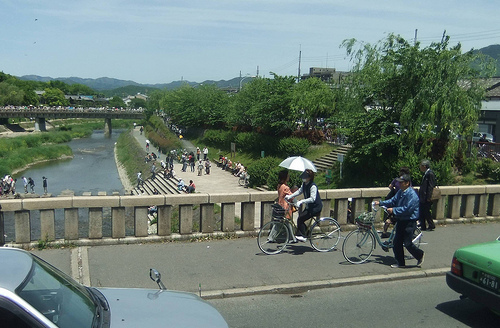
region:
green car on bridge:
[444, 235, 498, 312]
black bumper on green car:
[443, 269, 498, 305]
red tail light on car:
[448, 256, 462, 277]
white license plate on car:
[477, 272, 498, 287]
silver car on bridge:
[0, 245, 230, 326]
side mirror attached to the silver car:
[147, 267, 169, 292]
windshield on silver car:
[15, 253, 107, 325]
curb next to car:
[195, 263, 451, 300]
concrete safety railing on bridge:
[1, 193, 275, 247]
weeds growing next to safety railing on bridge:
[33, 237, 63, 253]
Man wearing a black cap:
[388, 171, 413, 188]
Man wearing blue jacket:
[373, 188, 440, 219]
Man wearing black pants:
[391, 215, 428, 278]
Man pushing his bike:
[337, 171, 437, 277]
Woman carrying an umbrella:
[270, 145, 322, 178]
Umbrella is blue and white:
[276, 149, 323, 180]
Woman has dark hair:
[271, 168, 298, 188]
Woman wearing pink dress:
[276, 185, 291, 222]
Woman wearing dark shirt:
[287, 168, 333, 203]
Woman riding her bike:
[261, 172, 341, 260]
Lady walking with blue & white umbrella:
[274, 156, 299, 192]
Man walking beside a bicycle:
[352, 176, 434, 271]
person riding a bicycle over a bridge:
[266, 169, 341, 234]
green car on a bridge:
[451, 234, 498, 296]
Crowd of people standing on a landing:
[161, 148, 255, 188]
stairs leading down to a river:
[318, 139, 343, 175]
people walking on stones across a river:
[0, 171, 55, 196]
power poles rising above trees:
[223, 61, 317, 81]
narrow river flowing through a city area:
[71, 125, 125, 196]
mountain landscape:
[20, 70, 182, 102]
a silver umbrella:
[274, 152, 320, 174]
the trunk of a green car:
[444, 225, 499, 298]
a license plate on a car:
[477, 268, 497, 288]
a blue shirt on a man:
[380, 185, 425, 220]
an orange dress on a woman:
[267, 180, 292, 221]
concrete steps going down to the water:
[125, 170, 197, 195]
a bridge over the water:
[5, 95, 165, 150]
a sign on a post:
[330, 150, 345, 177]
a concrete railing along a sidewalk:
[0, 180, 492, 240]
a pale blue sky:
[2, 4, 499, 84]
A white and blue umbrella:
[275, 147, 321, 202]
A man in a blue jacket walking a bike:
[335, 169, 432, 262]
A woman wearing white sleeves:
[261, 164, 340, 252]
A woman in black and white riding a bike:
[253, 166, 340, 256]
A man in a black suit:
[415, 157, 445, 237]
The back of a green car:
[436, 228, 495, 318]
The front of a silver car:
[0, 248, 234, 326]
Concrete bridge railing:
[2, 191, 223, 243]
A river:
[19, 125, 124, 226]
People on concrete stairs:
[125, 157, 197, 199]